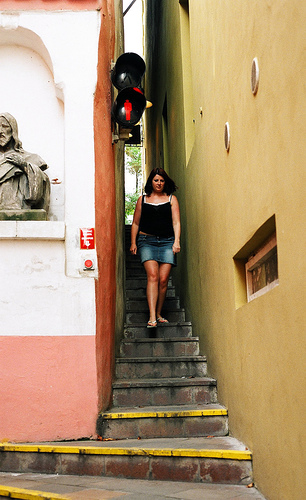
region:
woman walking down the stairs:
[126, 167, 184, 326]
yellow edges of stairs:
[0, 403, 250, 498]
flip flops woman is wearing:
[144, 317, 169, 327]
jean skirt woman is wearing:
[136, 229, 176, 262]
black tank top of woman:
[134, 193, 174, 237]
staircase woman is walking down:
[7, 218, 259, 498]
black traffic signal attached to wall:
[112, 49, 147, 126]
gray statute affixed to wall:
[1, 114, 53, 220]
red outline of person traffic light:
[121, 96, 131, 116]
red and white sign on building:
[79, 228, 93, 249]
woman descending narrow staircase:
[121, 171, 192, 319]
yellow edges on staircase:
[100, 407, 255, 423]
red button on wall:
[79, 256, 114, 277]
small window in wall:
[215, 232, 305, 296]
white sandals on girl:
[138, 313, 186, 341]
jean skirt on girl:
[136, 236, 188, 264]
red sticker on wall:
[68, 219, 99, 250]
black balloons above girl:
[111, 63, 154, 136]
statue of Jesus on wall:
[0, 107, 45, 210]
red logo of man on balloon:
[115, 96, 135, 129]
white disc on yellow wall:
[218, 120, 246, 159]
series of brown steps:
[126, 343, 200, 442]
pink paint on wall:
[19, 357, 60, 386]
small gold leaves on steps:
[81, 432, 115, 445]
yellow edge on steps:
[106, 440, 202, 457]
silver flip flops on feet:
[137, 313, 182, 330]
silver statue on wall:
[2, 113, 54, 218]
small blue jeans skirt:
[131, 233, 182, 262]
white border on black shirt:
[139, 190, 186, 214]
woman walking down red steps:
[127, 154, 187, 322]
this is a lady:
[123, 166, 189, 326]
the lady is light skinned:
[148, 266, 154, 286]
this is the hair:
[163, 171, 170, 191]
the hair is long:
[165, 171, 177, 185]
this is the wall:
[260, 71, 286, 175]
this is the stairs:
[140, 338, 165, 455]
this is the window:
[228, 251, 264, 290]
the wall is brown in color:
[236, 325, 285, 396]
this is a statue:
[5, 123, 40, 206]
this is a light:
[121, 75, 135, 132]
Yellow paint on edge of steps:
[1, 399, 251, 497]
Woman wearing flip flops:
[131, 307, 173, 330]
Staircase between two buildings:
[100, 221, 256, 490]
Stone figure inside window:
[0, 109, 56, 222]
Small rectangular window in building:
[226, 246, 284, 299]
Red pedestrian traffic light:
[96, 48, 151, 136]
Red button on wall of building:
[76, 255, 95, 272]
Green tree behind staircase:
[124, 145, 141, 222]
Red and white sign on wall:
[75, 225, 96, 248]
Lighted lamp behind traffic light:
[142, 90, 155, 114]